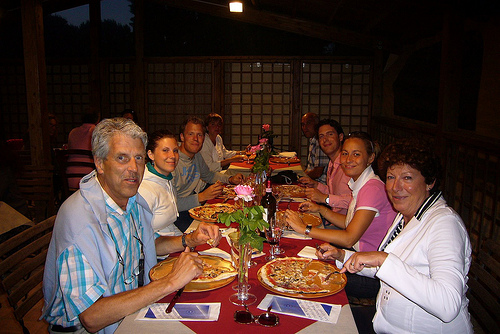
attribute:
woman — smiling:
[144, 131, 195, 251]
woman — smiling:
[286, 130, 399, 252]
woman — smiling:
[311, 140, 477, 333]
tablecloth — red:
[157, 230, 350, 333]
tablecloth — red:
[205, 180, 321, 228]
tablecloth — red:
[229, 144, 300, 172]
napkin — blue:
[256, 291, 343, 328]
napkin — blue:
[133, 297, 225, 323]